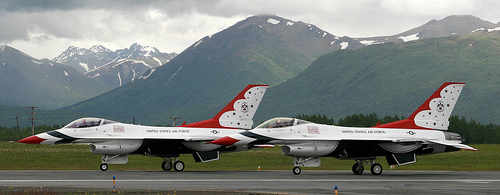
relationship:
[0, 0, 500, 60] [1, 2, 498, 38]
clouds in sky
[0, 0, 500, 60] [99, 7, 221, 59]
clouds in sky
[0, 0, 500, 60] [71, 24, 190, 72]
clouds in sky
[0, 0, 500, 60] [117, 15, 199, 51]
clouds in sky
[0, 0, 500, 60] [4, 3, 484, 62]
clouds in sky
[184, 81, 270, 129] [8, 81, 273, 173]
tail of plane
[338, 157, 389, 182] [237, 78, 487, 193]
gear of plane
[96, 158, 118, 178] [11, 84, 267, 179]
gear of plane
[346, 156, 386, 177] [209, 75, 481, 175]
landing gear of plane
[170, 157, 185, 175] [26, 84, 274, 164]
landing gear on jet plane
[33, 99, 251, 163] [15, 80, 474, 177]
men in jets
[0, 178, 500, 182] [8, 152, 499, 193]
line on runway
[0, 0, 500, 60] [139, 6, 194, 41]
clouds in sky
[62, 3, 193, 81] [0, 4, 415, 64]
clouds in sky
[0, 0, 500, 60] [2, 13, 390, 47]
clouds in sky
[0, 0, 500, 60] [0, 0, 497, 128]
clouds in sky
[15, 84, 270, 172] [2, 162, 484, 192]
jet on ground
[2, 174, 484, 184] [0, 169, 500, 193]
line dividing ground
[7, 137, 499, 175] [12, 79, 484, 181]
grass behind planes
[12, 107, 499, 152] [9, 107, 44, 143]
trees with poles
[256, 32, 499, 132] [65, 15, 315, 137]
mountains in front of mountains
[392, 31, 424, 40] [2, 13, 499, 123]
snow over mountains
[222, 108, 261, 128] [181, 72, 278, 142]
dots on red tail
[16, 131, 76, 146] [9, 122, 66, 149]
stripes over nose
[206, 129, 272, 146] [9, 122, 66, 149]
stripes over nose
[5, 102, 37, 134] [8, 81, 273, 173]
poles under plane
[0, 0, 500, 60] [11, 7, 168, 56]
clouds in sky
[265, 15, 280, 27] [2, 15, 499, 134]
snow on mountains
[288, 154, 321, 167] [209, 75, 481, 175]
landing gear on plane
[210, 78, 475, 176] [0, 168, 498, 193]
jet parked on concrete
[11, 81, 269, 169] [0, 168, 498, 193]
jet parked on concrete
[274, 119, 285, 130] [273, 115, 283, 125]
pilot wearing helmet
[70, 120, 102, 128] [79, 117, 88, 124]
men wearing helmet